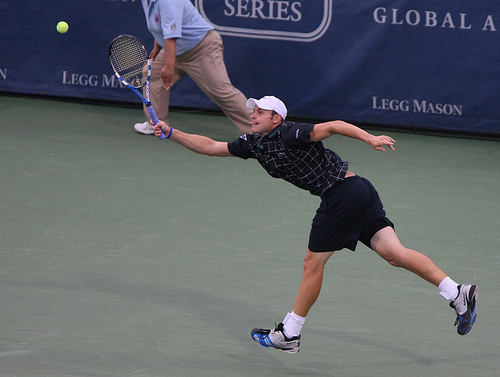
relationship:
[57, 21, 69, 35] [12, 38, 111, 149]
tennis ball in air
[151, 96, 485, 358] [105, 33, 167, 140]
person holding racket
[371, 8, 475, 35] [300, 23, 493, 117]
word on wall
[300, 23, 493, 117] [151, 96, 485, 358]
wall behind person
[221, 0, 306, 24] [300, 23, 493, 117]
word on wall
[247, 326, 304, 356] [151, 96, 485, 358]
left shoe on person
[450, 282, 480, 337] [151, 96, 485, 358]
right shoe on person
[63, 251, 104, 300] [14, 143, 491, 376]
part of court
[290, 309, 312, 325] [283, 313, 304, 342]
edge of sock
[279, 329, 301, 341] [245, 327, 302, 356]
edge of shoe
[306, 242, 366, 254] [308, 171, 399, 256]
edge of shorts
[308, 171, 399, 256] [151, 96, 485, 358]
shorts on person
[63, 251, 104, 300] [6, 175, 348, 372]
part of floor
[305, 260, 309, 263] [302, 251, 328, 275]
part of a knee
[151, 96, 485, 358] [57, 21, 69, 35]
person moving towards tennis ball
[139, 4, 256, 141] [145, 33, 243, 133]
person wearing pants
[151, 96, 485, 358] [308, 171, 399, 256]
person wearing shorts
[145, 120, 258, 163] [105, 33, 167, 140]
right arm holding racket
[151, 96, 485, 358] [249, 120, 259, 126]
person sticking out tongue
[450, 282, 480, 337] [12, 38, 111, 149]
right shoe in air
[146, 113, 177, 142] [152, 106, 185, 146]
hand in front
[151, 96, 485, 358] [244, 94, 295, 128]
person wearing a cap